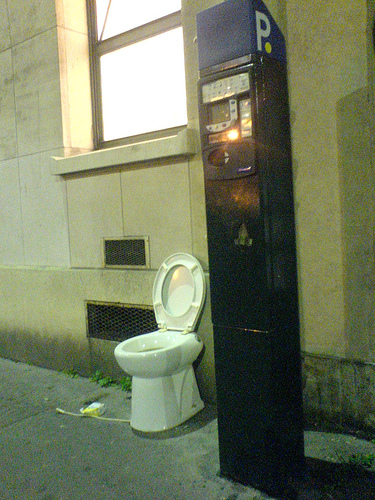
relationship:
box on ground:
[81, 402, 109, 415] [2, 357, 132, 498]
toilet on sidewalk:
[113, 252, 207, 433] [1, 357, 374, 499]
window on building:
[86, 1, 184, 151] [4, 0, 371, 359]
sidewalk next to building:
[1, 357, 374, 499] [4, 0, 371, 359]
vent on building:
[100, 238, 148, 269] [4, 0, 371, 359]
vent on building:
[84, 303, 158, 341] [4, 0, 371, 359]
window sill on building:
[56, 132, 195, 176] [4, 0, 371, 359]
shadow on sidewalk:
[302, 457, 373, 499] [1, 357, 374, 499]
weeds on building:
[65, 369, 131, 388] [4, 0, 371, 359]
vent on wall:
[100, 238, 148, 269] [4, 0, 371, 359]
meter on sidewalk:
[198, 1, 293, 478] [1, 357, 374, 499]